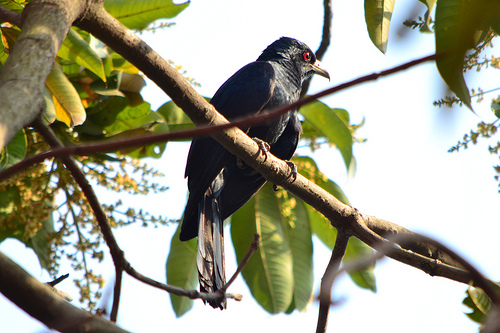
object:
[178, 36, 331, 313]
bird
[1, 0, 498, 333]
tree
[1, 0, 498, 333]
sky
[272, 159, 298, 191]
claw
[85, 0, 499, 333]
branch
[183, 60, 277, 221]
wing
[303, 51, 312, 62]
eye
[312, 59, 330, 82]
beak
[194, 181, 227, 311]
tail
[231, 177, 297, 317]
leaf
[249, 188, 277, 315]
vein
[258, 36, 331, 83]
head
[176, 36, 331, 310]
branch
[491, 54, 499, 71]
flower